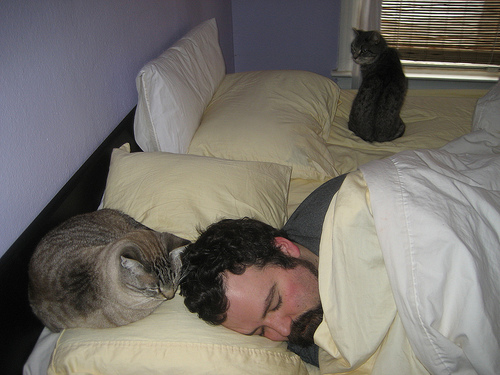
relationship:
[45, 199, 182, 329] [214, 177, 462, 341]
cat near man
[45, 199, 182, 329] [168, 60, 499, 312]
cat on bed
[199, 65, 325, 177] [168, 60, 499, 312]
pillow on bed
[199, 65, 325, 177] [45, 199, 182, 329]
pillow near cat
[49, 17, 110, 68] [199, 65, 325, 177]
wall near pillow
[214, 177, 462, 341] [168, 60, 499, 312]
man on bed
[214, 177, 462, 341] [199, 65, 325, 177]
man on pillow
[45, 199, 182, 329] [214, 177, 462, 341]
cat above man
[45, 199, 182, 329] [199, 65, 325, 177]
cat on pillow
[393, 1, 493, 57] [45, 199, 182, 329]
window near cat